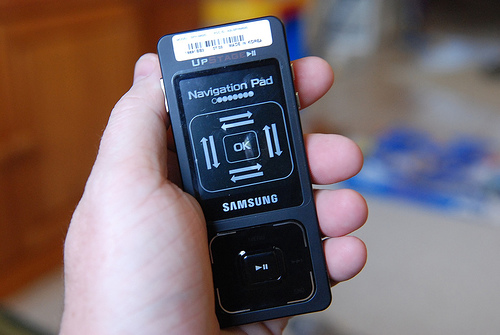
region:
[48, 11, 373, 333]
hand holding a black control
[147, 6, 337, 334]
control have a white label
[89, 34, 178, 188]
thumb with pink nail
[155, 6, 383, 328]
fingers color pink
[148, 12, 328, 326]
black remote in person's hand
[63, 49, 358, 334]
hand the remote is in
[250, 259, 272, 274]
play and pause symbols on the remote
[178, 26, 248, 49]
barcode on the remote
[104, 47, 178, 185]
thumb on the person's hand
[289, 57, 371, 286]
fingertips on the person's hand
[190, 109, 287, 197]
white arrows on the black remote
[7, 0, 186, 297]
wood furniture on the left side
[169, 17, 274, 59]
white sticker on the remote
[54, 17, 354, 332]
hand holding black control device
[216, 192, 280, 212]
brand logo on remote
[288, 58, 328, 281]
shadow on the fingertips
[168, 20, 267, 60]
black and white barcode on the remote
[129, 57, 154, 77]
thumbnail on the finger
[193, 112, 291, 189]
white arrows on the remote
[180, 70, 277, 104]
white lettering on the controller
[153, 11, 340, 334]
rectangle shaped black remote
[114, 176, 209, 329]
lines on the person's palm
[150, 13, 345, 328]
cell phone in hand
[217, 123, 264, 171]
middle button says ok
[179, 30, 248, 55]
barcode at top of phone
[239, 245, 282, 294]
button is play and pause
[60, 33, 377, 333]
left hand holding phone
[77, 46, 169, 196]
thumb is touching phone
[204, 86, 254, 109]
multiple circles on phone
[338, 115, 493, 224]
blue mat in background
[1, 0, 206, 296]
cabinet is wood and brown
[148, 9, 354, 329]
black cell phone being held in hand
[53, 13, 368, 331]
white hand holding Samsung cell phone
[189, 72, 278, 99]
navigation pad shown on phone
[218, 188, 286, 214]
brand name of Samsung printed across phone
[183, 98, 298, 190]
track pad show on phone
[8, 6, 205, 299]
blurry brown background wall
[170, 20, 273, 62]
white sticker with black bar code on phone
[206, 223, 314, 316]
black square section of phone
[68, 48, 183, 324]
thumb resting against side of phone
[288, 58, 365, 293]
four fingers holding cell phone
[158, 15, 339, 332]
black Samsung cell phone held in hand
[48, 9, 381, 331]
white hand holding black cell phone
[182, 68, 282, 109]
white navigation lettering on phone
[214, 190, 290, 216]
samsung name on black phone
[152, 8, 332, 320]
A mp3 player.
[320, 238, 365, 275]
A tip of a finger.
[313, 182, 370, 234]
A tip of a finger.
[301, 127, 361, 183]
A tip of a finger.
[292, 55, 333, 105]
A tip of a finger.